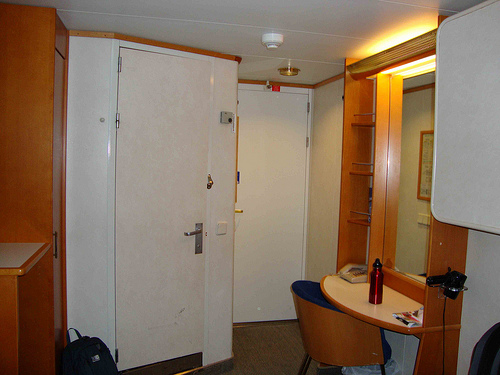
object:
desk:
[321, 272, 421, 333]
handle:
[183, 227, 207, 239]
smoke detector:
[259, 34, 283, 50]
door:
[113, 47, 213, 374]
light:
[367, 23, 435, 56]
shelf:
[351, 122, 376, 128]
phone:
[334, 260, 367, 285]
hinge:
[113, 349, 118, 364]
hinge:
[305, 136, 310, 147]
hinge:
[307, 100, 310, 115]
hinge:
[115, 112, 120, 127]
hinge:
[118, 55, 123, 73]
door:
[232, 87, 309, 322]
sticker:
[271, 85, 280, 93]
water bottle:
[369, 257, 384, 305]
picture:
[417, 132, 433, 201]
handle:
[52, 229, 59, 261]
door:
[51, 46, 66, 371]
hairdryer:
[427, 270, 467, 299]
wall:
[456, 227, 499, 374]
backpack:
[57, 326, 120, 374]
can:
[340, 357, 401, 374]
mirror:
[395, 70, 437, 283]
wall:
[305, 77, 346, 281]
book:
[391, 307, 425, 327]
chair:
[289, 279, 394, 374]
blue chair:
[290, 278, 393, 374]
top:
[369, 257, 385, 267]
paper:
[393, 307, 427, 328]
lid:
[370, 258, 383, 268]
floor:
[176, 320, 335, 374]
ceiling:
[2, 0, 490, 85]